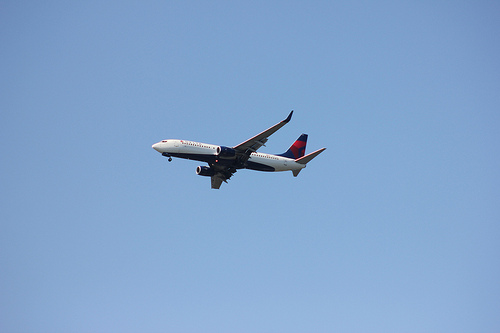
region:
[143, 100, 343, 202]
plane in mid air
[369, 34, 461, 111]
blue of daytime sky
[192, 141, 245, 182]
jet engines under wings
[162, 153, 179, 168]
wheel of landing gear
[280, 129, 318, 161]
blue and red tail of plane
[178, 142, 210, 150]
windows on side of plane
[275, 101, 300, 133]
upturned tip of plane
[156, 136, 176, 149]
windshield of plane cockpit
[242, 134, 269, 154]
underside of plane wing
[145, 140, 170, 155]
white nose on plane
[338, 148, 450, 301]
The sky is clear.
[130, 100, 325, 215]
The plane is in the air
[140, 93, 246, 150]
The plane is white.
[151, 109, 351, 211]
The plane is flying.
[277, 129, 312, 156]
The tail is blue and red.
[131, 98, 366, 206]
The plane is large.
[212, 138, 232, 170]
The jet is blue.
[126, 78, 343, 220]
The plane has people in it.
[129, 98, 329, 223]
The wheels are up.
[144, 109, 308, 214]
The wings are grey.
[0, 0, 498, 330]
Beautiful sunny blue sky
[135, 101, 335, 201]
Large passenger plane in flight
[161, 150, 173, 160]
Planes landing gear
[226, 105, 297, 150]
Planes left wing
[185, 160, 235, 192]
Planes right wing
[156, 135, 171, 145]
Window that the pilot uses to navigate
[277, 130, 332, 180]
Planes rudders and tail fins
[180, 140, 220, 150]
Passenger windows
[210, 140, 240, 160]
Passenger plane's left engine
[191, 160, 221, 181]
Passenger plane's right engine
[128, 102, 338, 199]
A plane in the air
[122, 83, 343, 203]
A plane flying in the air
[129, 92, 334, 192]
A white plane in the air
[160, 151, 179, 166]
A wheel on a plane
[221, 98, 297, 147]
A wing on a plane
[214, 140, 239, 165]
An engine on a plane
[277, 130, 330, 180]
The tail of a plane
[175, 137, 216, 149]
Windows on a plane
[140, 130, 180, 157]
The nose of an airplane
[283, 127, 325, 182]
Red and blue tail on an airplane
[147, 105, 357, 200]
Commercial Airplane for passengers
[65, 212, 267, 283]
Clear blue sky with no clouds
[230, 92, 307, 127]
Blue tip on the plane's wing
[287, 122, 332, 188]
Tail of the plane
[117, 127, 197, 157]
Tip of the plane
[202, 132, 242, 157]
Plane propeller that makes it fly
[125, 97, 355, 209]
Passenger airplane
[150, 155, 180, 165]
Landing wheel when on the ground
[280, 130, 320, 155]
Red and blue tail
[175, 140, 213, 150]
Passenger windows to look out of